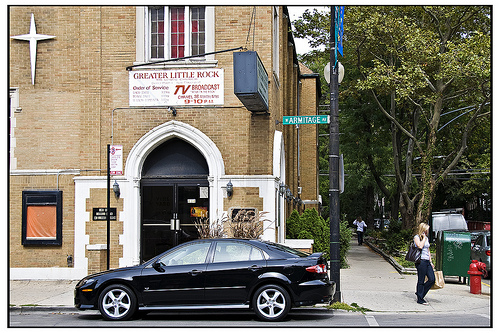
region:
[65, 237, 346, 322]
black sedan parked on the side of the road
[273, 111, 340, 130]
green street sign for Armitage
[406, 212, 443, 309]
woman wearing blue jeans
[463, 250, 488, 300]
red fire hydrant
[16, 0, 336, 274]
large brick building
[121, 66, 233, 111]
white sign with lots of words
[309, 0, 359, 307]
black pole with lots of street signs on it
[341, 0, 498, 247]
large, old green trees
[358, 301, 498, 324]
white stripes for a crosswalk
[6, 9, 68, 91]
white cross on the side of a building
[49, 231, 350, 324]
A BLACK CAR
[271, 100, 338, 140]
A GREEN STREET SIGN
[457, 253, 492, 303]
A RED FIRE HYDRANT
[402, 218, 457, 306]
WOMAN HOLDING A SHOPPING BAG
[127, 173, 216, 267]
TWO GLASS DOORS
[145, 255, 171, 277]
A SIDE VIEW MIRROR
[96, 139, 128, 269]
A PARKING SIGN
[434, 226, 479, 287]
A GREEN MAILBOX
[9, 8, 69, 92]
A CROSS ON A BUILDING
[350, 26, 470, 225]
A TREE IN THE BACKGROUND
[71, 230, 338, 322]
a black car parked in front of a building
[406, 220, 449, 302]
a woman carrying a bag talking on the phone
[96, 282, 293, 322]
the wheels of a car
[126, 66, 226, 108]
an advertisement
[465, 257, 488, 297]
a fire hydrant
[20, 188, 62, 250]
the window of a building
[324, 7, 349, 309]
a tall pole holding several signs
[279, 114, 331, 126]
a street sign denoted Armitage Avenue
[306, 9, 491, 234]
a row of lush trees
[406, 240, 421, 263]
a woman's large shoulder bag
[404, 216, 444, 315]
woman walking and talking on a cellphone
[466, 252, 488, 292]
red fire hydrant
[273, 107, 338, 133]
street sign with armitage on it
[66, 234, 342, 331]
black four door car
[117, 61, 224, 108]
sign with greater little rock written on it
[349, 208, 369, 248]
woman walking away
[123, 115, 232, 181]
archway over the door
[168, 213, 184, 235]
pair of door handles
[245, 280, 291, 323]
wheel with five spokes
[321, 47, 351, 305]
black pole with a light on it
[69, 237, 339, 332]
a parked four door car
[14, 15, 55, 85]
a white cross on a building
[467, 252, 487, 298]
a bright red fire hydrant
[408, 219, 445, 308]
a woman talking on a phone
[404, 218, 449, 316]
lady walking and talking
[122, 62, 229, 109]
a white advertisement sign on the side of building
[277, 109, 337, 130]
a green street sign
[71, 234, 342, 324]
a black four door car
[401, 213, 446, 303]
a blonde girl on the street corner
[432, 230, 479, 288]
two green mailboxes on the side of the street